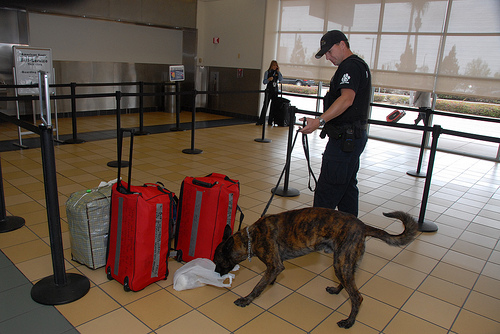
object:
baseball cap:
[313, 29, 347, 59]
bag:
[172, 256, 241, 290]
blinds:
[271, 0, 499, 163]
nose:
[214, 264, 225, 276]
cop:
[296, 28, 374, 220]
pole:
[39, 124, 69, 285]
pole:
[418, 125, 441, 224]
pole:
[115, 90, 122, 159]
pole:
[189, 92, 196, 149]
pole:
[261, 87, 268, 139]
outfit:
[312, 53, 373, 219]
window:
[373, 30, 445, 75]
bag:
[65, 175, 122, 269]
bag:
[104, 126, 175, 291]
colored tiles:
[0, 110, 500, 334]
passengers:
[255, 57, 285, 129]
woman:
[409, 91, 439, 127]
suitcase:
[384, 108, 405, 122]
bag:
[173, 172, 246, 267]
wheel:
[166, 249, 178, 260]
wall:
[0, 1, 209, 121]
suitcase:
[268, 81, 297, 125]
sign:
[10, 44, 53, 95]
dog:
[209, 207, 417, 330]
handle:
[231, 205, 244, 232]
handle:
[115, 127, 142, 190]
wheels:
[123, 275, 133, 292]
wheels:
[107, 265, 114, 280]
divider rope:
[0, 80, 500, 146]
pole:
[17, 123, 96, 313]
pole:
[283, 106, 295, 187]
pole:
[189, 85, 196, 149]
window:
[432, 33, 498, 101]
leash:
[247, 117, 320, 232]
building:
[0, 1, 499, 331]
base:
[30, 272, 91, 305]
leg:
[310, 131, 365, 217]